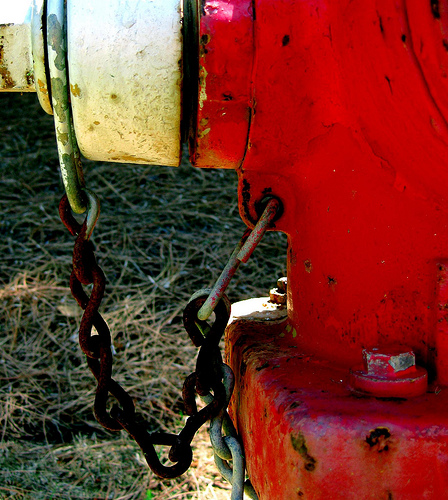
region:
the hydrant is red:
[321, 289, 423, 475]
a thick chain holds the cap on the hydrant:
[54, 186, 253, 486]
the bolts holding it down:
[354, 331, 437, 406]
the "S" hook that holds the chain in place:
[201, 192, 303, 326]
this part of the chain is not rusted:
[204, 361, 239, 479]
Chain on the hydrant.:
[45, 166, 268, 490]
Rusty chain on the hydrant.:
[44, 202, 314, 498]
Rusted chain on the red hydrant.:
[66, 214, 261, 481]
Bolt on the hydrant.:
[313, 291, 443, 440]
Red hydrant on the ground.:
[13, 5, 430, 458]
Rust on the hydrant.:
[249, 344, 321, 472]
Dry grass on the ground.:
[17, 283, 134, 436]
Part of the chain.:
[187, 413, 283, 494]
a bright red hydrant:
[245, 128, 429, 380]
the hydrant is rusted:
[272, 315, 422, 498]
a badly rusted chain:
[69, 279, 177, 457]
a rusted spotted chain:
[34, 52, 107, 222]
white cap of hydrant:
[58, 22, 186, 153]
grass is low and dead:
[11, 317, 110, 448]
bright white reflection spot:
[195, 256, 301, 356]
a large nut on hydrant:
[359, 345, 421, 407]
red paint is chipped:
[212, 102, 368, 377]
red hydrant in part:
[192, 17, 446, 490]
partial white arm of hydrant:
[0, 7, 190, 156]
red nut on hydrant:
[351, 349, 429, 398]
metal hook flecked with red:
[195, 199, 287, 314]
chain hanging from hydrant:
[56, 206, 246, 495]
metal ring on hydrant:
[43, 2, 85, 204]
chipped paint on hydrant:
[199, 67, 218, 137]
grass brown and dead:
[3, 119, 234, 498]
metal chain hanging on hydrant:
[203, 393, 249, 498]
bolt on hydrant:
[268, 275, 286, 305]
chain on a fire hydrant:
[36, 61, 254, 483]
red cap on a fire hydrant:
[340, 330, 432, 404]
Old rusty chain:
[73, 303, 209, 479]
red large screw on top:
[345, 342, 418, 392]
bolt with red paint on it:
[344, 335, 432, 403]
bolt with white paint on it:
[0, 0, 55, 139]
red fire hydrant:
[5, 1, 445, 497]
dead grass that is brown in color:
[2, 90, 284, 497]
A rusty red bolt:
[271, 272, 292, 304]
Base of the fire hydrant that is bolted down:
[223, 288, 438, 499]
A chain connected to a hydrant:
[0, 2, 446, 498]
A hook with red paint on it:
[188, 185, 282, 330]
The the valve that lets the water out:
[0, 1, 188, 171]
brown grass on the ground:
[42, 302, 180, 497]